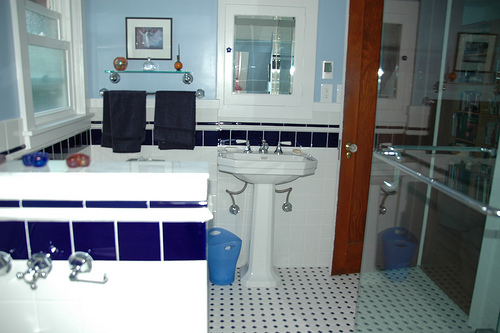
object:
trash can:
[208, 227, 243, 286]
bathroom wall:
[277, 216, 329, 267]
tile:
[207, 264, 461, 332]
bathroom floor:
[211, 284, 466, 333]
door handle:
[344, 141, 358, 158]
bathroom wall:
[316, 3, 344, 59]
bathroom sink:
[215, 152, 319, 289]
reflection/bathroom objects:
[385, 26, 480, 232]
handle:
[371, 143, 500, 219]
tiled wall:
[0, 174, 207, 333]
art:
[126, 17, 173, 61]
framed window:
[25, 8, 71, 114]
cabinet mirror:
[232, 10, 297, 95]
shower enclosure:
[379, 2, 484, 274]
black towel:
[154, 90, 196, 150]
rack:
[101, 90, 202, 99]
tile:
[0, 221, 205, 261]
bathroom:
[0, 0, 500, 333]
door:
[330, 0, 385, 276]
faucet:
[258, 140, 270, 154]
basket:
[207, 227, 242, 285]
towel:
[100, 91, 146, 155]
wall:
[279, 211, 334, 267]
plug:
[320, 84, 332, 103]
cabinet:
[218, 5, 316, 120]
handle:
[226, 47, 233, 53]